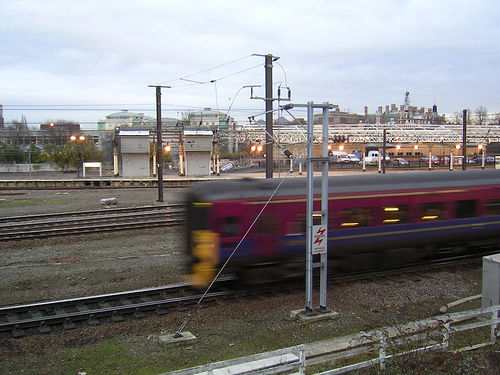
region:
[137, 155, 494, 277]
Train speeding down the track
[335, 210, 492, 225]
Windows on the side of the train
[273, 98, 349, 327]
Metal pole beside the track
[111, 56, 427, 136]
Power lines over the track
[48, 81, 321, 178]
Buildings on side of the track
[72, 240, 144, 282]
Gravel inbetween the track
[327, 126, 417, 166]
Cars parked on side of sidewalk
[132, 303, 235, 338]
The pole is held up with a line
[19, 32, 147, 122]
The sky is covered in clouds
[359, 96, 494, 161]
lights in front of the stand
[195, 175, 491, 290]
a purple and blue train mover very fast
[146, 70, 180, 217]
a tall electrical pole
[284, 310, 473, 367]
a small white fence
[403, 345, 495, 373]
a small bush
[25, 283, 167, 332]
some rail road tracks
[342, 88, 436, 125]
some large buildings in the distance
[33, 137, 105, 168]
some small trees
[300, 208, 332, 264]
a danger sign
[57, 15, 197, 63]
some skies with minor clouds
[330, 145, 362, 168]
some parked white vans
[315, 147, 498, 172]
Multiple vehicles parked in front of a building.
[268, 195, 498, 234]
Windows on the train.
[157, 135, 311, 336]
A stabilizing wire for the utility pole.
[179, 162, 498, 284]
A red, blue, and grey train.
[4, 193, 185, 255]
A set of railroad tracks.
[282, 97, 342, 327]
A grey utility pole.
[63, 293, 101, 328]
Wooden railroad ties under the tracks.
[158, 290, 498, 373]
A white fence near the tracks.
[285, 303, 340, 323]
A concrete footer for the utility pole to sit on.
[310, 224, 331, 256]
A sign indicating electrical hazard.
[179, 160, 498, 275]
A red, yellow, and blue train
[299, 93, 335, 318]
Two metal posts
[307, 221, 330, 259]
A white sign with red lighting bolts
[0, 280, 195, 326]
A line of train tracks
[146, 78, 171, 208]
A wooden electrical pole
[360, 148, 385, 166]
A white vehicle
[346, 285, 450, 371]
A small green shrub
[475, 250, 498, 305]
A gray metal box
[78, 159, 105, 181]
A white sign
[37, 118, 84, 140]
A square brick building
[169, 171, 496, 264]
train speeding down tracks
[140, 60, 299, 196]
brown utility poles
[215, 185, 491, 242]
windows along side of train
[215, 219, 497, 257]
blue stripe on side of train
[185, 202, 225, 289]
yellow on front of train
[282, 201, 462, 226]
lights inside of train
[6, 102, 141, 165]
buildings in background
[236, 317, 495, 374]
railing along train tracks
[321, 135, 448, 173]
cars parked in parking lot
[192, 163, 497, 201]
gray top of train